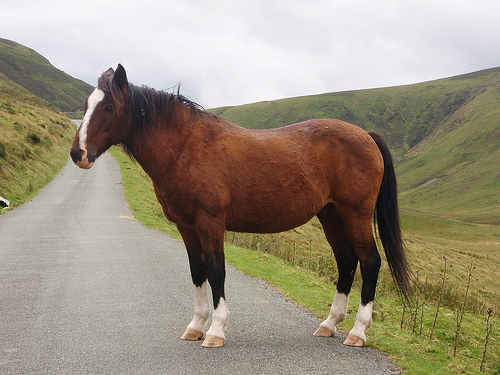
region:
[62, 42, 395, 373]
this is a horse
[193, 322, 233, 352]
the front left hoof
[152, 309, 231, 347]
the front right hoof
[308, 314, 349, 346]
the back right hoof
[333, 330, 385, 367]
the back left hoof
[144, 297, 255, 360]
the two front hooves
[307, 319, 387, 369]
the two back hooves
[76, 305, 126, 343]
this is gray concrete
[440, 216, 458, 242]
this is green grass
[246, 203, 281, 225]
this is the color brown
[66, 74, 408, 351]
a brown and white horse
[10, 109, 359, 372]
a long paved road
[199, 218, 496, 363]
a long wire fence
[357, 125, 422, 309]
a horse black tail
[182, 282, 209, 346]
a front right hoof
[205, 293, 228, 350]
a front left hoof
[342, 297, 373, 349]
a rear left hoof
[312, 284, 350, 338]
a rear right hoof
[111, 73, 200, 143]
a horse's black mane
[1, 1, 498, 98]
a cloudy grey sky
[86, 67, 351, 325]
a horse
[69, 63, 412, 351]
a horse standing in the road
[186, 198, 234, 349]
a brown, black and beige horse leg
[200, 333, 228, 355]
a horse hoove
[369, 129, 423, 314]
a long horse tail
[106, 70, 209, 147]
a horses mane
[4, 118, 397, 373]
a long road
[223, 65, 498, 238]
a green hill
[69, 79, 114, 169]
a long horse face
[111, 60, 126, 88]
a horse ear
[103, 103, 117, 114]
a small black horse eye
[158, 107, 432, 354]
a horse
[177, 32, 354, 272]
a horse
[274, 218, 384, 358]
a horse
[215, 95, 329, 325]
a horse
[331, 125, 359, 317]
a horse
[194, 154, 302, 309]
a horse